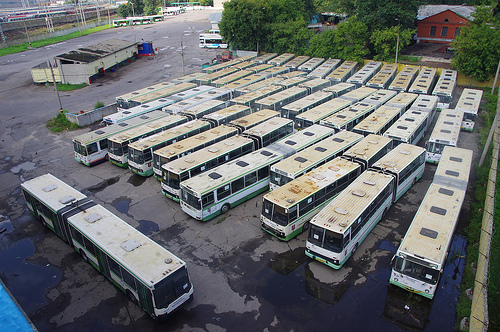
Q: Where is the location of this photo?
A: A parking lot.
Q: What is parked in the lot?
A: Buses.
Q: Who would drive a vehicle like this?
A: A bus driver.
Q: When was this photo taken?
A: Daytime.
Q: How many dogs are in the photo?
A: Zero.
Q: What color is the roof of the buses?
A: White.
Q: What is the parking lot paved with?
A: Asphalt.